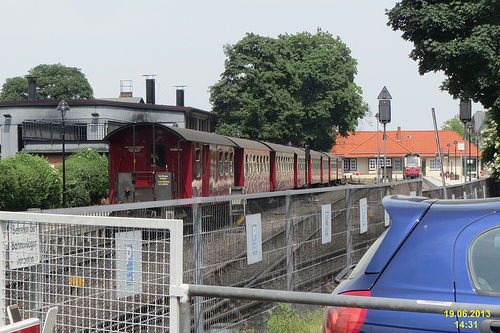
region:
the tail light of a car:
[315, 283, 374, 331]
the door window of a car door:
[467, 222, 498, 300]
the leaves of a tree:
[432, 11, 493, 57]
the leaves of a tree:
[263, 52, 320, 123]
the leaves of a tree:
[37, 75, 79, 92]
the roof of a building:
[341, 130, 453, 155]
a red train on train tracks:
[106, 109, 349, 200]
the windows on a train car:
[245, 150, 273, 177]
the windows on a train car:
[215, 145, 235, 181]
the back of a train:
[101, 121, 191, 225]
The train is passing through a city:
[10, 33, 457, 329]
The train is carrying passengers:
[45, 41, 460, 311]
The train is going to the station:
[15, 55, 465, 295]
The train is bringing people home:
[27, 51, 488, 313]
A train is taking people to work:
[15, 55, 480, 290]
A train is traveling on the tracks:
[15, 65, 481, 311]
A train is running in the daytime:
[27, 28, 463, 328]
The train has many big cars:
[10, 45, 480, 286]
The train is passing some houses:
[11, 30, 491, 310]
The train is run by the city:
[18, 60, 461, 302]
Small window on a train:
[145, 140, 178, 185]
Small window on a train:
[183, 142, 204, 189]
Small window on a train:
[211, 146, 234, 188]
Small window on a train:
[242, 151, 268, 179]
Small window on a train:
[274, 152, 294, 177]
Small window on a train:
[311, 156, 320, 178]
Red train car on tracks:
[102, 102, 233, 219]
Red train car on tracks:
[229, 115, 276, 213]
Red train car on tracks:
[261, 129, 297, 211]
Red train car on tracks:
[286, 143, 314, 198]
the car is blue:
[297, 182, 498, 326]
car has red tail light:
[297, 258, 373, 330]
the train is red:
[100, 104, 367, 212]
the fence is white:
[0, 206, 204, 331]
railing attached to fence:
[1, 214, 495, 328]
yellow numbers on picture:
[429, 288, 491, 330]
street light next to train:
[33, 73, 95, 212]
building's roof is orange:
[306, 116, 482, 175]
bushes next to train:
[0, 131, 122, 217]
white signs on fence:
[0, 178, 487, 275]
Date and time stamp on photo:
[441, 308, 491, 331]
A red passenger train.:
[109, 115, 343, 207]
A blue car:
[312, 187, 497, 323]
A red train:
[402, 148, 422, 177]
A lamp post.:
[45, 99, 85, 210]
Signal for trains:
[371, 82, 393, 192]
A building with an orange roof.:
[331, 117, 478, 180]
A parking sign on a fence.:
[112, 226, 156, 298]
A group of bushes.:
[5, 155, 107, 203]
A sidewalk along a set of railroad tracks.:
[421, 166, 465, 200]